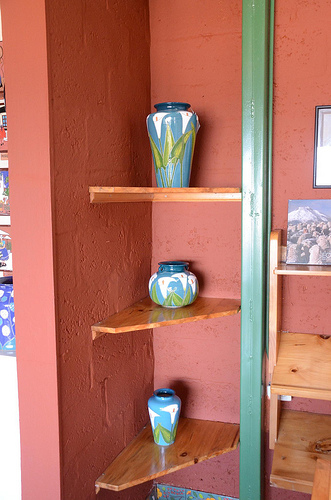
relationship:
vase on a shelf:
[145, 99, 200, 189] [88, 186, 242, 200]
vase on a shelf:
[149, 260, 199, 307] [89, 293, 240, 338]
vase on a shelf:
[147, 387, 181, 445] [94, 415, 239, 489]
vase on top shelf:
[145, 99, 200, 189] [88, 187, 242, 203]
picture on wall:
[312, 106, 328, 186] [48, 3, 326, 491]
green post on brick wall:
[239, 0, 277, 499] [2, 1, 331, 500]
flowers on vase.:
[151, 109, 191, 181] [123, 83, 224, 210]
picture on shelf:
[284, 199, 330, 265] [270, 261, 330, 274]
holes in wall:
[59, 237, 122, 281] [3, 0, 153, 497]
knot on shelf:
[178, 450, 189, 458] [94, 415, 239, 489]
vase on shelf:
[143, 92, 202, 183] [87, 183, 239, 202]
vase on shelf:
[147, 387, 181, 445] [91, 296, 240, 341]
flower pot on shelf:
[138, 95, 209, 187] [87, 183, 239, 202]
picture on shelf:
[284, 199, 330, 265] [274, 266, 329, 279]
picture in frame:
[312, 106, 331, 186] [310, 103, 329, 190]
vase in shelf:
[147, 387, 181, 445] [94, 415, 239, 489]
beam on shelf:
[238, 0, 276, 498] [21, 14, 312, 445]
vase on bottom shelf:
[144, 386, 180, 445] [94, 415, 239, 489]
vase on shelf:
[145, 99, 200, 189] [87, 183, 239, 202]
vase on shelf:
[149, 260, 199, 309] [96, 292, 243, 333]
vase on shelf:
[147, 387, 181, 445] [95, 427, 235, 490]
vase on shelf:
[147, 387, 181, 445] [94, 415, 239, 489]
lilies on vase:
[168, 269, 189, 290] [143, 258, 203, 308]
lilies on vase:
[160, 402, 179, 435] [141, 382, 183, 445]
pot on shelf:
[146, 259, 200, 310] [89, 288, 240, 342]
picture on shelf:
[289, 199, 329, 265] [269, 235, 328, 349]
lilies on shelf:
[150, 110, 167, 143] [87, 183, 239, 202]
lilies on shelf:
[174, 109, 191, 159] [87, 183, 239, 202]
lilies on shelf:
[157, 274, 174, 301] [89, 293, 240, 338]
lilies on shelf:
[168, 269, 189, 290] [89, 293, 240, 338]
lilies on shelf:
[160, 402, 179, 435] [90, 417, 242, 494]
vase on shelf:
[147, 387, 181, 445] [104, 301, 218, 462]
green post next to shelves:
[228, 45, 277, 265] [99, 179, 236, 207]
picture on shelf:
[284, 199, 330, 265] [268, 229, 330, 499]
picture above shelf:
[312, 106, 331, 186] [268, 228, 330, 275]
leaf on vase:
[168, 129, 192, 163] [131, 87, 215, 201]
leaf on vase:
[163, 121, 175, 169] [131, 87, 215, 201]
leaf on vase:
[146, 132, 167, 173] [131, 87, 215, 201]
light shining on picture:
[311, 141, 329, 186] [307, 104, 328, 191]